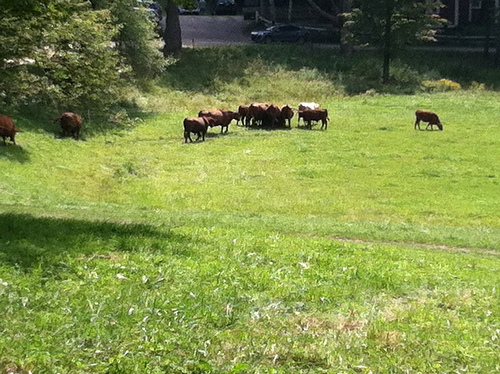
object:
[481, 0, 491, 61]
trunk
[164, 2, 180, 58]
trunk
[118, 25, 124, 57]
trunk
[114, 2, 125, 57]
tree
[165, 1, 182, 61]
tree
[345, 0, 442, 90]
tree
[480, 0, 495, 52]
tree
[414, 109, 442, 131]
cow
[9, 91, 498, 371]
short grass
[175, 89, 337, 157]
cow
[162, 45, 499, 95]
weeds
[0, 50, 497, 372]
pasture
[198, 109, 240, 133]
cow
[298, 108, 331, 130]
cow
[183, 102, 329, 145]
cows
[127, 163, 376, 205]
grass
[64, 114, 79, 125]
brown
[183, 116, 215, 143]
cow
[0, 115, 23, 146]
cow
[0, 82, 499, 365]
green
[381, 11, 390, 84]
trunk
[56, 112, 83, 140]
cow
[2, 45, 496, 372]
grass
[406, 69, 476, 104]
flowers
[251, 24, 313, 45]
sedan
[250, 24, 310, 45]
car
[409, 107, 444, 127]
cow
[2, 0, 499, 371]
field